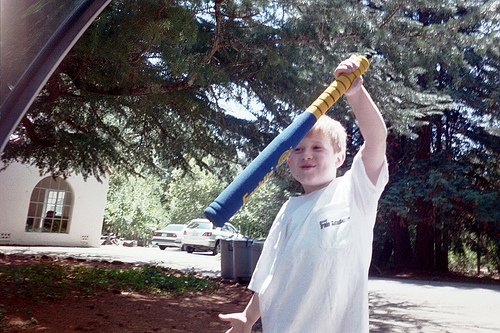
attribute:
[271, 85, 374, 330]
boy — blonde, smiling, happy, white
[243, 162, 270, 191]
bat — blue, yellow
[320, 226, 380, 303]
shirt — white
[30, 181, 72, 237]
window — open, white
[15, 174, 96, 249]
building — white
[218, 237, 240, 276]
trash can — grey, gray